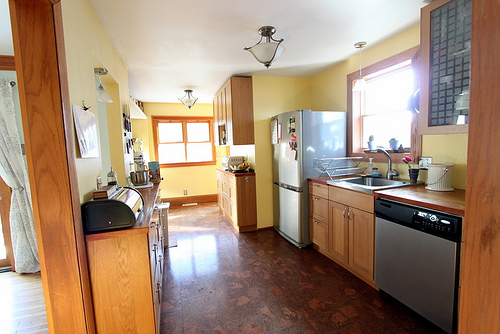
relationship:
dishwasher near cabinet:
[381, 220, 446, 304] [323, 210, 365, 263]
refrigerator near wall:
[276, 125, 304, 224] [257, 85, 270, 100]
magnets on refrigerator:
[287, 119, 297, 151] [276, 125, 304, 224]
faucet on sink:
[384, 160, 393, 177] [345, 176, 391, 189]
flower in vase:
[401, 158, 413, 164] [408, 168, 417, 183]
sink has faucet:
[345, 176, 391, 189] [384, 160, 393, 177]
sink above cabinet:
[345, 176, 391, 189] [323, 210, 365, 263]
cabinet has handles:
[323, 210, 365, 263] [342, 209, 350, 223]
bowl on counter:
[132, 170, 149, 183] [148, 192, 154, 201]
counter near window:
[148, 192, 154, 201] [158, 117, 213, 162]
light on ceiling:
[257, 29, 280, 64] [151, 30, 204, 68]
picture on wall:
[78, 109, 87, 156] [257, 85, 270, 100]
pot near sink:
[426, 166, 453, 189] [345, 176, 391, 189]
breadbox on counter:
[116, 198, 134, 219] [148, 192, 154, 201]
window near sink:
[158, 117, 213, 162] [345, 176, 391, 189]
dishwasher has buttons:
[381, 220, 446, 304] [421, 214, 451, 229]